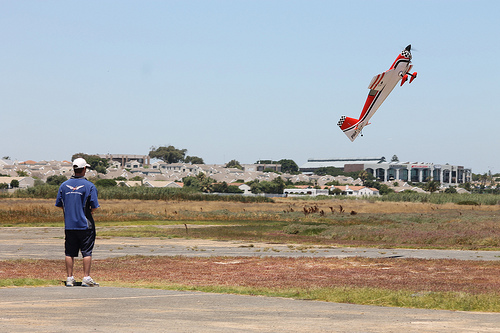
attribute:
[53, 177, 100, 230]
shirt — blue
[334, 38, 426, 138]
plane — red, white, large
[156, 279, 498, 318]
grass — green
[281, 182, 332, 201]
building — white, small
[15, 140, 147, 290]
man — standing outside